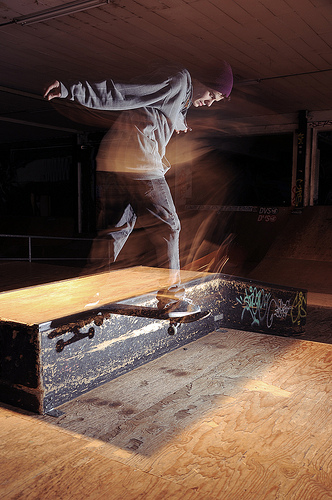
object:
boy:
[43, 52, 233, 320]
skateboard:
[92, 300, 212, 336]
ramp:
[246, 207, 332, 295]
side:
[41, 276, 220, 410]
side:
[218, 274, 308, 340]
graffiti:
[288, 288, 306, 327]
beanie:
[190, 52, 234, 100]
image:
[0, 0, 332, 498]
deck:
[0, 262, 224, 331]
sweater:
[60, 62, 193, 172]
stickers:
[256, 204, 279, 221]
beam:
[0, 262, 225, 420]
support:
[92, 300, 212, 324]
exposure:
[0, 56, 235, 418]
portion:
[221, 275, 308, 338]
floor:
[4, 327, 332, 499]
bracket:
[45, 406, 64, 418]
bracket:
[216, 321, 232, 333]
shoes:
[169, 296, 202, 318]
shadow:
[34, 323, 300, 460]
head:
[187, 55, 233, 109]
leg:
[125, 178, 181, 295]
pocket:
[130, 177, 153, 202]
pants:
[79, 170, 181, 308]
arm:
[58, 72, 188, 112]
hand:
[43, 77, 64, 103]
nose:
[206, 99, 216, 108]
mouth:
[198, 99, 204, 106]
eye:
[206, 88, 213, 97]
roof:
[0, 0, 332, 115]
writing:
[264, 297, 294, 328]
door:
[210, 133, 294, 207]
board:
[217, 271, 308, 339]